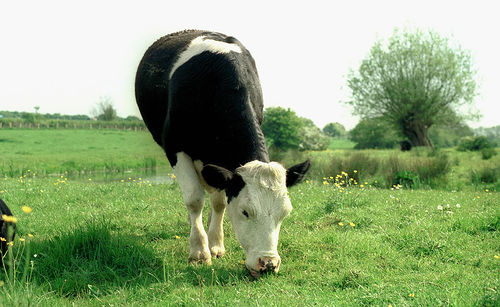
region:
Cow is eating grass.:
[100, 15, 325, 297]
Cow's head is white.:
[197, 145, 307, 295]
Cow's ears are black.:
[199, 145, 313, 200]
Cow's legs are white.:
[162, 147, 235, 276]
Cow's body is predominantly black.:
[121, 10, 283, 185]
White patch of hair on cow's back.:
[133, 12, 280, 156]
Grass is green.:
[5, 137, 477, 302]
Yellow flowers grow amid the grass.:
[0, 200, 79, 304]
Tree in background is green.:
[343, 13, 498, 185]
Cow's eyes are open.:
[194, 155, 322, 233]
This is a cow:
[101, 20, 316, 285]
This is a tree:
[337, 9, 484, 166]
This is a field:
[7, 93, 144, 176]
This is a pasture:
[3, 104, 494, 305]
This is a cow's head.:
[189, 121, 308, 291]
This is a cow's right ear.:
[192, 154, 239, 202]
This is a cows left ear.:
[261, 149, 317, 189]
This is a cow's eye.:
[231, 205, 258, 223]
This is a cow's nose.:
[245, 249, 293, 281]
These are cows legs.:
[162, 166, 232, 270]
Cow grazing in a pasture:
[2, 5, 484, 295]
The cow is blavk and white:
[117, 22, 328, 294]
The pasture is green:
[8, 104, 495, 294]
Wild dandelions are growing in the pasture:
[0, 135, 445, 301]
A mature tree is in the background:
[11, 2, 492, 277]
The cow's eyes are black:
[171, 160, 346, 300]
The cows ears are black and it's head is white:
[182, 140, 335, 277]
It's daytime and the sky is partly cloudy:
[21, 6, 476, 302]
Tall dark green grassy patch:
[6, 205, 157, 301]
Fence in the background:
[8, 95, 131, 172]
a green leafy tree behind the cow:
[346, 20, 478, 156]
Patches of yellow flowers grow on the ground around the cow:
[0, 165, 382, 305]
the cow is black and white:
[128, 27, 320, 279]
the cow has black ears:
[201, 154, 314, 196]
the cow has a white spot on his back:
[163, 30, 245, 85]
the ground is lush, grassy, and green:
[0, 110, 499, 305]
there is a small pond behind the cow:
[13, 153, 247, 192]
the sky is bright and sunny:
[3, 0, 498, 138]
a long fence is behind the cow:
[1, 119, 155, 133]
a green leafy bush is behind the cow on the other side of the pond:
[258, 104, 313, 154]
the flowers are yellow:
[322, 163, 363, 204]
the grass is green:
[329, 222, 434, 286]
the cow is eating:
[175, 123, 324, 295]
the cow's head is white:
[208, 150, 336, 281]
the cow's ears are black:
[197, 150, 327, 198]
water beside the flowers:
[49, 162, 156, 185]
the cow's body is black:
[129, 33, 271, 211]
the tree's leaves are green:
[359, 50, 444, 131]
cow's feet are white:
[161, 152, 236, 282]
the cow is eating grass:
[240, 204, 284, 302]